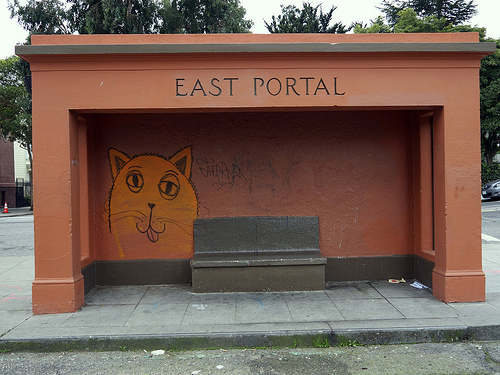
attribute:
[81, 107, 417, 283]
back wall — bus stop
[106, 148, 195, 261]
cat — drawing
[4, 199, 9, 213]
traffic cone — orange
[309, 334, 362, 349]
weeds — growing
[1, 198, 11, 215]
cone — orange, traffic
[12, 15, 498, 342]
stop — peach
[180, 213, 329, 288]
bench — cement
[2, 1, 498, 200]
trees — showing, above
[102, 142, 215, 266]
cat — orange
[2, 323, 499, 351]
curb — street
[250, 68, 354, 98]
portal — word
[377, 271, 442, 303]
trash — under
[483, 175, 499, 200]
car — silver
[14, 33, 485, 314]
shelter — over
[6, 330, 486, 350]
curb — concrete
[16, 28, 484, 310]
portal — east, wall